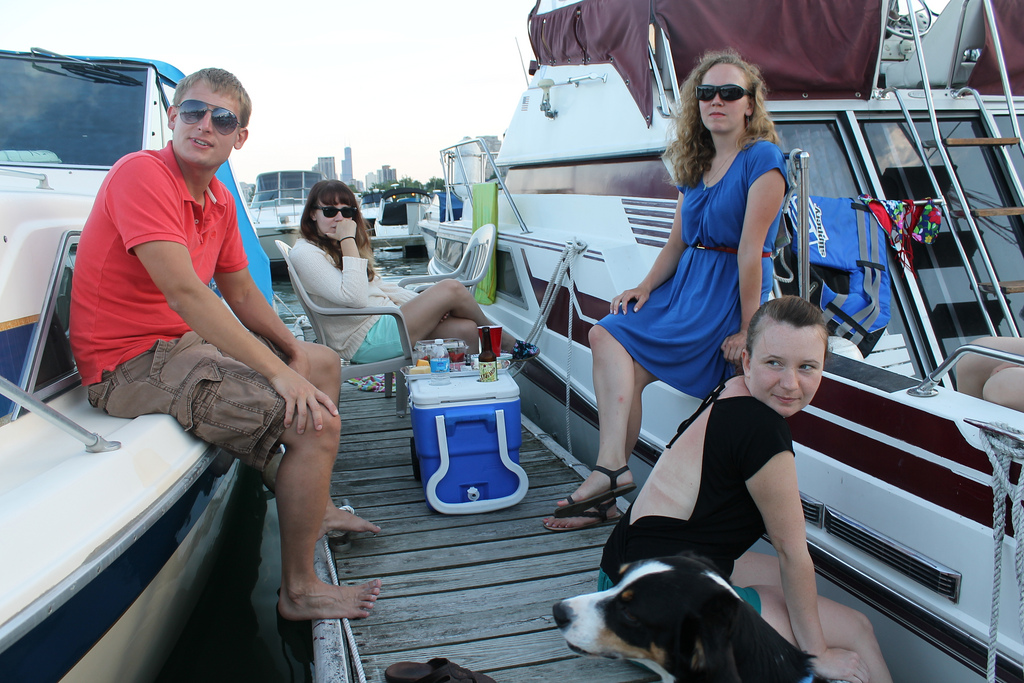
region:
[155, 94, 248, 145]
man has sunglasses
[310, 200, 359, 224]
woman has sunglasses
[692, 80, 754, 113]
woman has sunglasses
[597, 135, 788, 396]
woman is wearing a blue dress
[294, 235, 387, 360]
woman is wearing a white top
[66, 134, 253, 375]
man is wearing a red polo shirt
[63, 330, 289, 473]
man is wearing brown shorts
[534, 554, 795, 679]
black, white and brown dog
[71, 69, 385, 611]
a man is sitting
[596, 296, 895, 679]
a woman is sitting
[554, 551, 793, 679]
head of a dog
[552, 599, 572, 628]
the nose is black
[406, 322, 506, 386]
a group of drinks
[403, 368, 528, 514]
white and blue cooler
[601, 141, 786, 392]
the dress is blue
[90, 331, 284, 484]
the shorts are brown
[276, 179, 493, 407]
woman sitting in chair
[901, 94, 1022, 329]
ladder on the boat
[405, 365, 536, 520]
Box is blue and white color.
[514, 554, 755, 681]
Dog is black, white and brown color.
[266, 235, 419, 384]
Chair is grey color.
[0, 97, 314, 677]
Boats are in water.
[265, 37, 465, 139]
Sky is white color.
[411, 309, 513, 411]
Bottle is in top of the box.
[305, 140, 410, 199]
Buildings are behind the boats.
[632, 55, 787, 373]
Woman is wearing black eye glass.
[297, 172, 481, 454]
Woman is sitting in the chair.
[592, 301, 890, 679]
girl wearing a black tank top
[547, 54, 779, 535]
woman wearing a blue dress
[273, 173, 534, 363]
woman sitting in a chair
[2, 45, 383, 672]
man sitting on a boat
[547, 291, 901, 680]
girl sitting next to a black and white dog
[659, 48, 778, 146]
woman wearing black sunglasses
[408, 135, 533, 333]
raft hanging on the side of a boat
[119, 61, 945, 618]
these are a group of people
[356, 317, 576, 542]
this is a cooler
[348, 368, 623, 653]
the cooler is blue and white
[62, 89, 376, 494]
the man is sitting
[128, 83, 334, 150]
the man has sunglasses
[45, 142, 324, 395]
the polo is red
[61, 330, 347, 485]
the shorts are khaki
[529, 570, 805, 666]
the dog is black and white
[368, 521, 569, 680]
the docks are wooden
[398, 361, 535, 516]
A white and blue cooler.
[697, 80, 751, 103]
A pair of black sunglasses.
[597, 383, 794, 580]
An open back t shirt.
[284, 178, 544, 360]
A woman sitting on a chair.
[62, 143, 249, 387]
A bright pink tee shirt.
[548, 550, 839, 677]
A brown and white dog.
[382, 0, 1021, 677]
A large white and brown boat.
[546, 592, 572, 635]
A small black dog nose.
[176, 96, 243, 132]
A pair of black sunglasses.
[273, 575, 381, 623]
A right human foot.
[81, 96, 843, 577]
this is a group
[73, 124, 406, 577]
the man is sitting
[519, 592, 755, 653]
the dog is black and white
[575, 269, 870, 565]
the dress is black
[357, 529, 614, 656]
the dock is wooden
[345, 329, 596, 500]
the cooler are blue and white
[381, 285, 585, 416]
the drinks are on the cooler